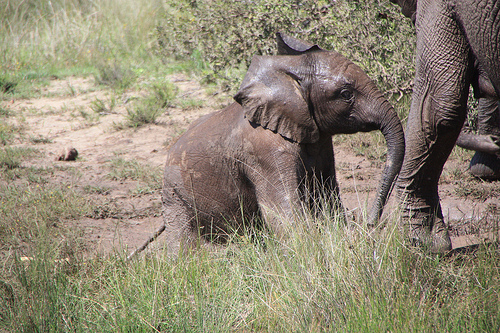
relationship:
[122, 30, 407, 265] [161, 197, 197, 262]
elephant has hind leg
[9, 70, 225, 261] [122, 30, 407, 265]
dirt behind elephant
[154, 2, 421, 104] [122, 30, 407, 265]
bush behind elephant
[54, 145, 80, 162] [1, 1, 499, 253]
rock sitting on ground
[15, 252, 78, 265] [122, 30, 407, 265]
branch behind elephant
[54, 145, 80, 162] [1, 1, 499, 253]
rock laying on ground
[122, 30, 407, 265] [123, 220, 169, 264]
elephant has tail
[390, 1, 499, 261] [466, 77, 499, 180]
elephant has left leg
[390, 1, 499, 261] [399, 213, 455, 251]
elephant has foot